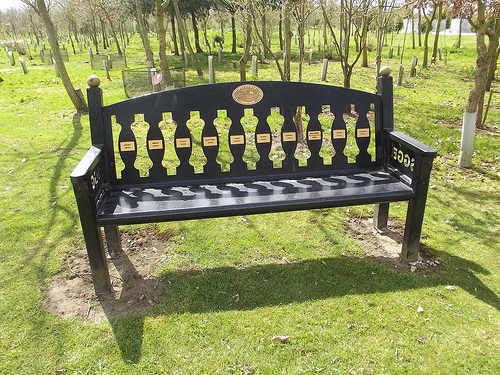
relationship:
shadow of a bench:
[91, 237, 499, 365] [68, 68, 440, 291]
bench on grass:
[68, 68, 440, 291] [5, 34, 497, 374]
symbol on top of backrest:
[232, 83, 264, 105] [101, 80, 381, 184]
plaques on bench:
[354, 104, 371, 164] [68, 68, 440, 291]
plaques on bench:
[329, 107, 350, 167] [68, 68, 440, 291]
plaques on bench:
[303, 105, 324, 167] [68, 68, 440, 291]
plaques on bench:
[278, 104, 296, 166] [68, 68, 440, 291]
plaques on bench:
[247, 107, 274, 169] [68, 68, 440, 291]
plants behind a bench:
[2, 0, 499, 127] [68, 68, 440, 291]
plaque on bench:
[117, 140, 136, 152] [68, 68, 440, 291]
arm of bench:
[63, 140, 108, 185] [68, 68, 440, 291]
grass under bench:
[5, 34, 497, 374] [68, 68, 440, 291]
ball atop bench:
[86, 72, 101, 87] [68, 68, 440, 291]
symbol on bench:
[220, 79, 262, 114] [68, 68, 440, 291]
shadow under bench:
[91, 237, 499, 365] [68, 68, 440, 291]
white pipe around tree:
[457, 110, 479, 169] [443, 1, 499, 169]